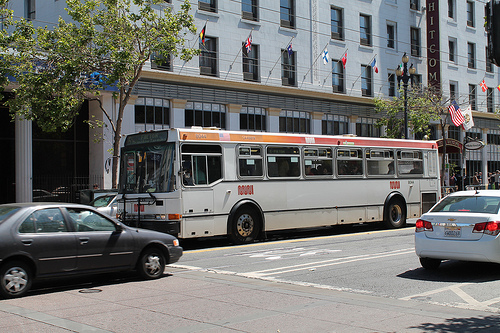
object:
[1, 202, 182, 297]
car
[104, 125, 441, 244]
bus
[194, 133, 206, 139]
number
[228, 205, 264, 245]
wheel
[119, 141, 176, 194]
front window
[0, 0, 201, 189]
tree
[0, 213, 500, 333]
road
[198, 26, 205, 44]
flag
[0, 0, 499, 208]
building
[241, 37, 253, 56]
flag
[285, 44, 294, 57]
flag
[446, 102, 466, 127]
american flag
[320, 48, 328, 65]
flag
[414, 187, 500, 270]
white car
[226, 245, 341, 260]
letters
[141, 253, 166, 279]
wheel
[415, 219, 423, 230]
brake light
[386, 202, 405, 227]
tire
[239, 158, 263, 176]
window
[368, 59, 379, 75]
flag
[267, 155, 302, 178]
window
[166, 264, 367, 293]
white marking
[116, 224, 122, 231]
side mirror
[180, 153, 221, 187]
window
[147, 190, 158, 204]
windshield wiper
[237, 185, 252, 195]
red numbers